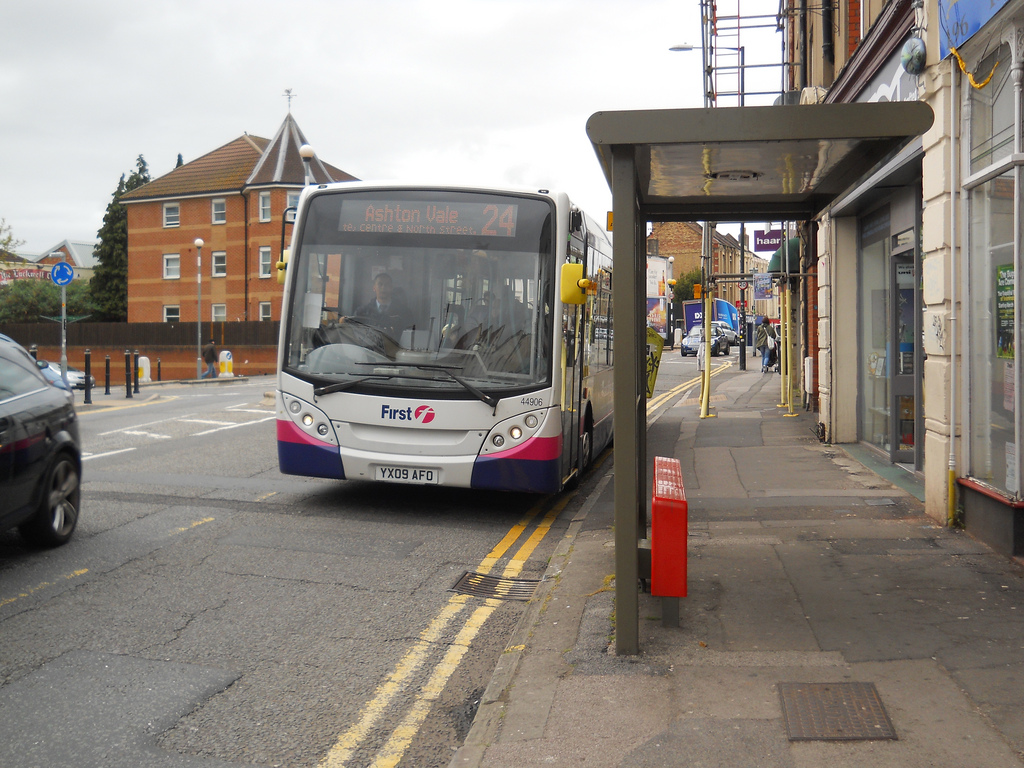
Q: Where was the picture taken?
A: It was taken at the road.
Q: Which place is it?
A: It is a road.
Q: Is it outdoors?
A: Yes, it is outdoors.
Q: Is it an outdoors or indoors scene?
A: It is outdoors.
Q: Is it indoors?
A: No, it is outdoors.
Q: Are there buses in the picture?
A: Yes, there is a bus.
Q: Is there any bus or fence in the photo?
A: Yes, there is a bus.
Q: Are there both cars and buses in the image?
A: Yes, there are both a bus and a car.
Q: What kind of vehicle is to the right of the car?
A: The vehicle is a bus.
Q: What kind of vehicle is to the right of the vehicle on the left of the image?
A: The vehicle is a bus.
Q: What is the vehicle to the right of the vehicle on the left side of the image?
A: The vehicle is a bus.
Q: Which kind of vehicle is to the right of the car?
A: The vehicle is a bus.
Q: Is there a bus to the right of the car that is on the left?
A: Yes, there is a bus to the right of the car.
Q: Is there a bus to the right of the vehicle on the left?
A: Yes, there is a bus to the right of the car.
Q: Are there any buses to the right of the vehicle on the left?
A: Yes, there is a bus to the right of the car.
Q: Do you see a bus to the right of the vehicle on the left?
A: Yes, there is a bus to the right of the car.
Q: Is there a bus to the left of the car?
A: No, the bus is to the right of the car.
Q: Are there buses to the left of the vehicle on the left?
A: No, the bus is to the right of the car.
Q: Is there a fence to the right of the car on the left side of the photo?
A: No, there is a bus to the right of the car.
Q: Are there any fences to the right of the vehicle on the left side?
A: No, there is a bus to the right of the car.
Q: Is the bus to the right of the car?
A: Yes, the bus is to the right of the car.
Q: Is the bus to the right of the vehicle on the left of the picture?
A: Yes, the bus is to the right of the car.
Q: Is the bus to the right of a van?
A: No, the bus is to the right of the car.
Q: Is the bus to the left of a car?
A: No, the bus is to the right of a car.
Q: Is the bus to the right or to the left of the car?
A: The bus is to the right of the car.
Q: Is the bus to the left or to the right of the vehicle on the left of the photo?
A: The bus is to the right of the car.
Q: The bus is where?
A: The bus is at the bus stop.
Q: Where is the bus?
A: The bus is at the bus stop.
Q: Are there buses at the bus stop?
A: Yes, there is a bus at the bus stop.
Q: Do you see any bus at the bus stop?
A: Yes, there is a bus at the bus stop.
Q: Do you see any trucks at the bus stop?
A: No, there is a bus at the bus stop.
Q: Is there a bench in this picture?
A: No, there are no benches.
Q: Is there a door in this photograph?
A: Yes, there is a door.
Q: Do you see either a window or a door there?
A: Yes, there is a door.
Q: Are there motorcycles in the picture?
A: No, there are no motorcycles.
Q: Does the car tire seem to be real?
A: Yes, the tire is real.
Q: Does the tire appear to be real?
A: Yes, the tire is real.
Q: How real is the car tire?
A: The tire is real.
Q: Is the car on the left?
A: Yes, the car is on the left of the image.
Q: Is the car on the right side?
A: No, the car is on the left of the image.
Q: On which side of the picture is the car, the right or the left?
A: The car is on the left of the image.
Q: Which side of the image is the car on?
A: The car is on the left of the image.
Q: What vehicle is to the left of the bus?
A: The vehicle is a car.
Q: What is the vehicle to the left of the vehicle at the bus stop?
A: The vehicle is a car.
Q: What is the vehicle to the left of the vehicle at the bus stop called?
A: The vehicle is a car.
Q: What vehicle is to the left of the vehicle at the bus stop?
A: The vehicle is a car.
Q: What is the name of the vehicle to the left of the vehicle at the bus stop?
A: The vehicle is a car.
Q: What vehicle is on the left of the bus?
A: The vehicle is a car.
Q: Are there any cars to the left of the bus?
A: Yes, there is a car to the left of the bus.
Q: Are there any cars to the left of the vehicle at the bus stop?
A: Yes, there is a car to the left of the bus.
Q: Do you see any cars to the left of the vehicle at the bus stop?
A: Yes, there is a car to the left of the bus.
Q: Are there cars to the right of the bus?
A: No, the car is to the left of the bus.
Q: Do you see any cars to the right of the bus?
A: No, the car is to the left of the bus.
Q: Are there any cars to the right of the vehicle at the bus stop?
A: No, the car is to the left of the bus.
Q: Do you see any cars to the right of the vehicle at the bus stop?
A: No, the car is to the left of the bus.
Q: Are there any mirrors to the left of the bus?
A: No, there is a car to the left of the bus.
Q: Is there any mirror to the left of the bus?
A: No, there is a car to the left of the bus.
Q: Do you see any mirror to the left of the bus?
A: No, there is a car to the left of the bus.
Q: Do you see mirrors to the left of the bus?
A: No, there is a car to the left of the bus.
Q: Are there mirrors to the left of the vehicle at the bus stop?
A: No, there is a car to the left of the bus.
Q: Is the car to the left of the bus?
A: Yes, the car is to the left of the bus.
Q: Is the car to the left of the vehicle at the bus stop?
A: Yes, the car is to the left of the bus.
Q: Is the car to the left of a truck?
A: No, the car is to the left of the bus.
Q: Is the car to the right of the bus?
A: No, the car is to the left of the bus.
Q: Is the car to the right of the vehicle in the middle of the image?
A: No, the car is to the left of the bus.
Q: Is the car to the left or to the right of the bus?
A: The car is to the left of the bus.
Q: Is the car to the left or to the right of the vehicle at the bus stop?
A: The car is to the left of the bus.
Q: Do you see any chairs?
A: No, there are no chairs.